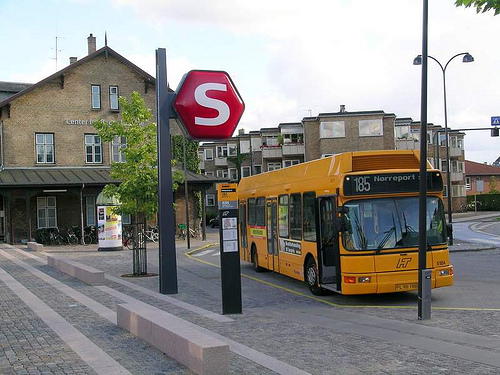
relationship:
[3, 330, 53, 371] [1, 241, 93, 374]
cobblestones on ground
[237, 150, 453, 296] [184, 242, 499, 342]
bus next to curb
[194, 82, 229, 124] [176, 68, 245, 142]
letter s on sign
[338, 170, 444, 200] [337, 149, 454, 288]
marquee display on bus front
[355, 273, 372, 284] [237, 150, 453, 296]
headlight on bus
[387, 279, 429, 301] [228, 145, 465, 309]
license plate on bus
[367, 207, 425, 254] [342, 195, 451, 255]
windshield wipers on front window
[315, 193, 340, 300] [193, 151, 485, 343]
door of bus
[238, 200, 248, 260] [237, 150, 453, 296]
door in back of bus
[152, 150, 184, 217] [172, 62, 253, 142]
pole holding sign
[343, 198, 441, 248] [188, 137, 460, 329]
front window of bus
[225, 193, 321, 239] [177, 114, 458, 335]
windows on bus